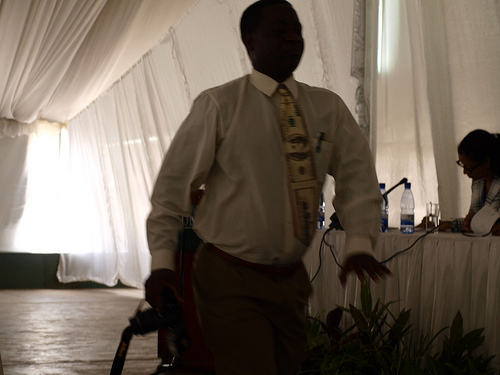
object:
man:
[145, 1, 393, 307]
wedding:
[0, 2, 499, 373]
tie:
[273, 88, 318, 244]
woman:
[415, 129, 499, 235]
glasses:
[456, 159, 464, 167]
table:
[303, 223, 499, 360]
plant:
[342, 294, 397, 375]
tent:
[0, 2, 500, 289]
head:
[240, 2, 305, 75]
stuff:
[316, 132, 324, 152]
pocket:
[315, 141, 335, 183]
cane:
[111, 324, 136, 374]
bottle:
[401, 183, 414, 233]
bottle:
[378, 182, 388, 232]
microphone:
[382, 176, 410, 197]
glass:
[425, 203, 438, 233]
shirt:
[147, 70, 383, 274]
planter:
[434, 317, 489, 371]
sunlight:
[7, 123, 107, 249]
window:
[7, 114, 148, 251]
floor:
[0, 286, 158, 374]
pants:
[186, 232, 308, 374]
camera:
[127, 295, 175, 335]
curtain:
[1, 0, 156, 288]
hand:
[145, 270, 179, 310]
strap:
[133, 296, 149, 313]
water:
[428, 215, 439, 230]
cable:
[311, 224, 339, 283]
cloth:
[314, 235, 500, 359]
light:
[108, 284, 145, 294]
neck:
[258, 70, 295, 85]